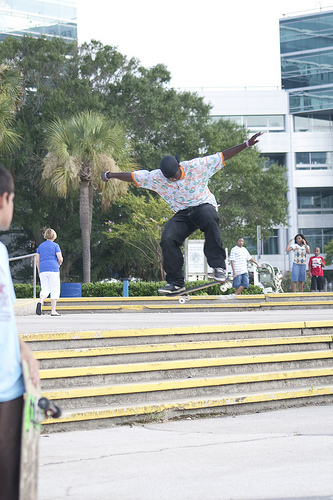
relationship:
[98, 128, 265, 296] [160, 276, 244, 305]
man on skateboard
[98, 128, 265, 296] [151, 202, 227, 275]
man wears pants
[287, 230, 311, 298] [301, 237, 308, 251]
woman on phone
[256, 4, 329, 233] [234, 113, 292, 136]
building has windows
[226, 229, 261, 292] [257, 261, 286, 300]
boy pushes stroller